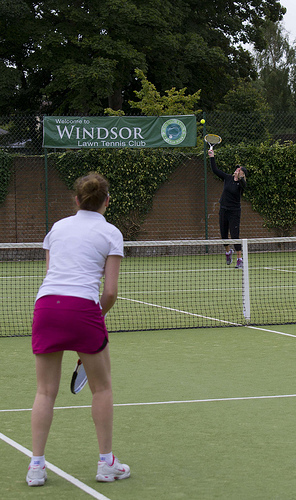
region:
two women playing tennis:
[16, 110, 254, 489]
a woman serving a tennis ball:
[195, 115, 254, 275]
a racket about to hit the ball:
[196, 116, 222, 163]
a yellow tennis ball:
[197, 116, 206, 126]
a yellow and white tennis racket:
[204, 129, 221, 149]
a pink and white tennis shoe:
[89, 454, 133, 483]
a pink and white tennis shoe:
[14, 449, 52, 488]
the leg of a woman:
[24, 349, 63, 486]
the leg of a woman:
[92, 350, 130, 486]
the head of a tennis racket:
[64, 350, 88, 400]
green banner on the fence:
[43, 116, 197, 148]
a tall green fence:
[3, 116, 295, 250]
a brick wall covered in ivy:
[4, 150, 294, 251]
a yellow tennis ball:
[200, 117, 204, 122]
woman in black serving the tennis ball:
[204, 133, 245, 270]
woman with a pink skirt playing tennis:
[27, 173, 130, 483]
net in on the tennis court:
[2, 236, 295, 337]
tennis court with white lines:
[0, 264, 290, 499]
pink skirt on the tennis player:
[30, 295, 109, 354]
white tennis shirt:
[36, 209, 122, 300]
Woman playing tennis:
[26, 171, 130, 483]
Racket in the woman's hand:
[69, 357, 88, 394]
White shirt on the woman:
[34, 208, 124, 308]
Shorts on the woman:
[31, 293, 109, 353]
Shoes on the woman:
[26, 453, 131, 485]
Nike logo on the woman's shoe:
[116, 465, 125, 471]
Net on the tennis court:
[0, 235, 295, 337]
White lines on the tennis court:
[0, 264, 295, 498]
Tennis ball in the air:
[200, 117, 205, 123]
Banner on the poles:
[40, 112, 198, 148]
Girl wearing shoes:
[21, 456, 139, 485]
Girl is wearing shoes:
[19, 460, 141, 487]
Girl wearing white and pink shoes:
[19, 454, 137, 484]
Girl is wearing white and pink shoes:
[21, 454, 135, 486]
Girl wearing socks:
[27, 446, 117, 471]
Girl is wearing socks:
[28, 451, 116, 470]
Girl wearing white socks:
[30, 449, 115, 468]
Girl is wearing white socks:
[23, 450, 115, 467]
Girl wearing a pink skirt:
[24, 291, 119, 354]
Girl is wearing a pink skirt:
[28, 291, 110, 358]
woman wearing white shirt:
[24, 200, 127, 312]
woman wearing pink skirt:
[27, 288, 118, 361]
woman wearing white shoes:
[14, 436, 136, 491]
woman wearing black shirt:
[207, 157, 251, 212]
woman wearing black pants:
[211, 197, 247, 251]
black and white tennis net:
[4, 201, 286, 341]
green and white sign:
[40, 107, 207, 164]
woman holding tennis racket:
[191, 111, 248, 193]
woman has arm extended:
[191, 118, 240, 184]